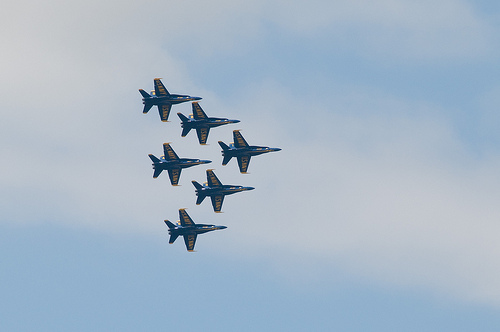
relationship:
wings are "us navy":
[171, 205, 203, 252] [178, 209, 195, 244]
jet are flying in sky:
[163, 207, 228, 252] [0, 6, 492, 326]